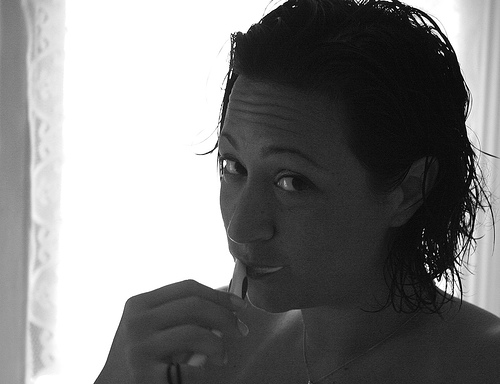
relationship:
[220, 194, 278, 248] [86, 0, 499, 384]
nose of girl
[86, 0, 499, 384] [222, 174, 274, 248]
girl has nose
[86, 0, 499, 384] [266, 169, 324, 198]
girl has eye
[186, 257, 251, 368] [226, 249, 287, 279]
toothbrush in mouth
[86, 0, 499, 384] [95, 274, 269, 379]
girl has hand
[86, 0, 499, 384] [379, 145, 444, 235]
girl has ear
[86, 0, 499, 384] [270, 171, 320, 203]
girl has eye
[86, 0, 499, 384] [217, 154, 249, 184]
girl has eye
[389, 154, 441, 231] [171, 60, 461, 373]
ear on girl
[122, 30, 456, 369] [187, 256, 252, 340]
girl with toothbrush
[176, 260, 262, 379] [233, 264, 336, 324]
toothbrush in mouth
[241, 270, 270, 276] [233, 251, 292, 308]
toothpaste on lip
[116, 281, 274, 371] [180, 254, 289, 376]
hand on toothbrush